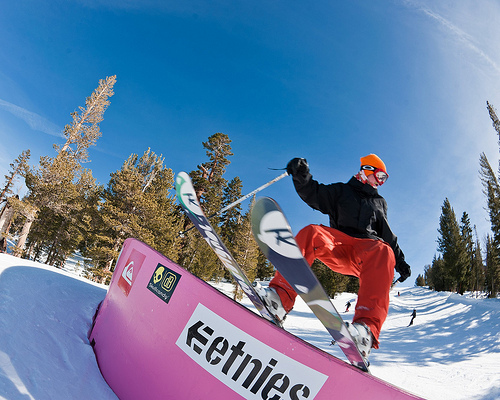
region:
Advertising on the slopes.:
[172, 301, 327, 398]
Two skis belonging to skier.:
[173, 170, 375, 373]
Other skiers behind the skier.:
[336, 282, 428, 329]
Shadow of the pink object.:
[4, 258, 116, 398]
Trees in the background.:
[2, 65, 498, 304]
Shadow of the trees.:
[250, 277, 499, 398]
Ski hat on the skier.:
[356, 152, 388, 188]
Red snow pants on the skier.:
[264, 219, 397, 346]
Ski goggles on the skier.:
[357, 160, 392, 187]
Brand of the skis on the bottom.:
[175, 187, 324, 308]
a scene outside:
[5, 3, 497, 393]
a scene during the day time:
[0, 0, 492, 399]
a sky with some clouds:
[3, 1, 497, 286]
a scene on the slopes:
[3, 3, 497, 388]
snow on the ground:
[2, 179, 496, 399]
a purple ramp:
[57, 205, 438, 396]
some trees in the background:
[3, 59, 344, 341]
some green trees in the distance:
[387, 86, 494, 337]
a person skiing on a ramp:
[146, 116, 446, 383]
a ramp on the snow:
[0, 178, 392, 390]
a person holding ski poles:
[177, 111, 469, 333]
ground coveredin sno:
[382, 291, 476, 358]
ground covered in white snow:
[426, 312, 485, 342]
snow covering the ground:
[402, 303, 475, 390]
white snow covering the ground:
[389, 268, 493, 375]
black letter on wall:
[186, 320, 212, 355]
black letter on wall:
[201, 333, 227, 370]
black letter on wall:
[220, 339, 245, 382]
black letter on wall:
[234, 353, 260, 391]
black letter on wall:
[249, 357, 279, 396]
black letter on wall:
[258, 371, 288, 398]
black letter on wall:
[286, 382, 311, 397]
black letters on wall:
[183, 320, 308, 399]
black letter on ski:
[265, 220, 294, 254]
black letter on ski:
[183, 190, 198, 207]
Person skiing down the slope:
[406, 303, 418, 326]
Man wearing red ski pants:
[268, 224, 395, 349]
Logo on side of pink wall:
[176, 301, 329, 398]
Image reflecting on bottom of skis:
[173, 170, 368, 375]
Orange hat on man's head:
[360, 154, 385, 174]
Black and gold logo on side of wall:
[145, 263, 182, 305]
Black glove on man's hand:
[287, 153, 307, 176]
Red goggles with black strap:
[361, 162, 388, 184]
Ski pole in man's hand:
[166, 155, 310, 240]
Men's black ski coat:
[291, 175, 403, 254]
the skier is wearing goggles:
[355, 152, 387, 184]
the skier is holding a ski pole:
[171, 151, 306, 249]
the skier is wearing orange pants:
[272, 218, 389, 344]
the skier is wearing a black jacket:
[288, 155, 409, 265]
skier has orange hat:
[344, 140, 383, 188]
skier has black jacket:
[304, 153, 409, 266]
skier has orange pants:
[259, 223, 396, 300]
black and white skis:
[181, 178, 361, 353]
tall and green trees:
[31, 83, 267, 285]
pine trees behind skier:
[360, 155, 497, 295]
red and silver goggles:
[336, 161, 406, 202]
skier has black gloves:
[289, 125, 462, 335]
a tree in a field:
[3, 140, 33, 214]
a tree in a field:
[18, 69, 111, 272]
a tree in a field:
[95, 145, 174, 287]